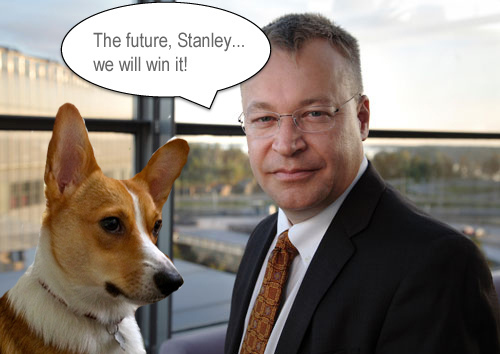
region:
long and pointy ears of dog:
[36, 95, 201, 201]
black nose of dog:
[149, 259, 189, 297]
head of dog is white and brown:
[55, 175, 191, 316]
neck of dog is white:
[14, 257, 119, 344]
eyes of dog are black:
[91, 208, 168, 241]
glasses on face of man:
[232, 92, 362, 137]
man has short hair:
[196, 5, 439, 274]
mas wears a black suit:
[185, 5, 497, 349]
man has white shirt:
[198, 11, 486, 352]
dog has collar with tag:
[33, 272, 135, 352]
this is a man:
[197, 10, 477, 340]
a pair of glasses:
[229, 92, 379, 160]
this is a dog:
[13, 78, 223, 350]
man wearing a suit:
[197, 148, 485, 350]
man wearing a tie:
[245, 205, 320, 349]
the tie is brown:
[247, 181, 309, 348]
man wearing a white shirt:
[222, 125, 378, 351]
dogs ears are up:
[23, 85, 203, 215]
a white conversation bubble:
[43, 10, 318, 111]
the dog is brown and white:
[12, 74, 202, 345]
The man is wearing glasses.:
[198, 11, 497, 352]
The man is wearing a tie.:
[193, 13, 498, 352]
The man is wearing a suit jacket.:
[208, 1, 499, 348]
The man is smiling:
[203, 5, 498, 352]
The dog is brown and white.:
[0, 95, 199, 352]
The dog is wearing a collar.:
[2, 96, 194, 350]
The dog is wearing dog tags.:
[0, 94, 210, 351]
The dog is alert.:
[0, 95, 202, 350]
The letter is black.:
[91, 25, 105, 50]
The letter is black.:
[171, 22, 188, 51]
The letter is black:
[90, 28, 101, 50]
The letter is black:
[99, 28, 113, 48]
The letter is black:
[109, 32, 121, 49]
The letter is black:
[123, 27, 132, 51]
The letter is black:
[129, 31, 140, 46]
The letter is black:
[137, 28, 144, 51]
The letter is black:
[141, 31, 151, 49]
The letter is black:
[152, 34, 158, 48]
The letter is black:
[156, 30, 169, 48]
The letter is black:
[174, 27, 187, 49]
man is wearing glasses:
[238, 109, 341, 131]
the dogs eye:
[97, 207, 127, 239]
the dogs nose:
[150, 267, 184, 297]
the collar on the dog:
[53, 292, 72, 311]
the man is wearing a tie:
[248, 306, 273, 326]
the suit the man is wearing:
[347, 251, 412, 312]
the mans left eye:
[302, 107, 324, 121]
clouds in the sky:
[386, 17, 446, 69]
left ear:
[153, 146, 185, 178]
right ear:
[54, 113, 82, 145]